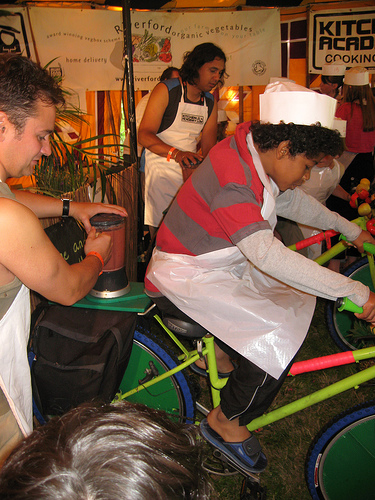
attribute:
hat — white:
[259, 75, 339, 131]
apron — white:
[1, 255, 35, 432]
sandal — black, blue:
[197, 420, 273, 496]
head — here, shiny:
[3, 407, 180, 498]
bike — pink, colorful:
[92, 253, 375, 495]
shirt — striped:
[150, 129, 266, 278]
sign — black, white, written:
[308, 8, 374, 73]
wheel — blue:
[296, 407, 374, 493]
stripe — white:
[239, 380, 271, 426]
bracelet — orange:
[86, 250, 108, 273]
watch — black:
[59, 197, 78, 216]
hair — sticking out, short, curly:
[246, 121, 338, 164]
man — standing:
[0, 56, 119, 440]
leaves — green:
[39, 57, 144, 230]